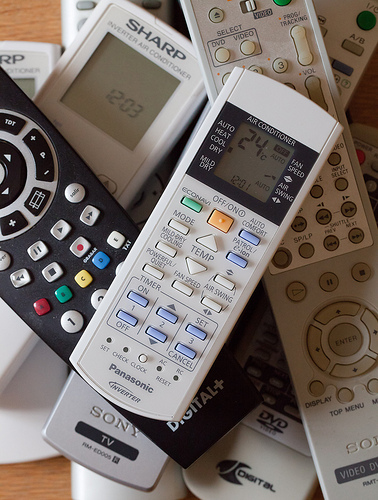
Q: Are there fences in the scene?
A: No, there are no fences.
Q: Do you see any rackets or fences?
A: No, there are no fences or rackets.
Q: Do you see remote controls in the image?
A: Yes, there is a remote control.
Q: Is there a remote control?
A: Yes, there is a remote control.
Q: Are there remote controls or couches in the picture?
A: Yes, there is a remote control.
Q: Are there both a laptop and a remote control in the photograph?
A: No, there is a remote control but no laptops.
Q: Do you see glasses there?
A: No, there are no glasses.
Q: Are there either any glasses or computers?
A: No, there are no glasses or computers.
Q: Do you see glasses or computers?
A: No, there are no glasses or computers.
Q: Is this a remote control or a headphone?
A: This is a remote control.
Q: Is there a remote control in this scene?
A: Yes, there is a remote control.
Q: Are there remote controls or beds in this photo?
A: Yes, there is a remote control.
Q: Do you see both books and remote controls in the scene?
A: No, there is a remote control but no books.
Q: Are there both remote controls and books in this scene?
A: No, there is a remote control but no books.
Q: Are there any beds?
A: No, there are no beds.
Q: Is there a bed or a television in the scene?
A: No, there are no beds or televisions.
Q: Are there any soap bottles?
A: No, there are no soap bottles.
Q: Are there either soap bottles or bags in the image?
A: No, there are no soap bottles or bags.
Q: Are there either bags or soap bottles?
A: No, there are no soap bottles or bags.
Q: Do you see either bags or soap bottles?
A: No, there are no soap bottles or bags.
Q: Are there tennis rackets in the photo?
A: No, there are no tennis rackets.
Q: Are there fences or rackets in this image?
A: No, there are no rackets or fences.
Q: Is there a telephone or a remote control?
A: Yes, there is a remote control.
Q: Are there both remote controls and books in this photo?
A: No, there is a remote control but no books.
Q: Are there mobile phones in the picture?
A: No, there are no mobile phones.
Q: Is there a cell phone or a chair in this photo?
A: No, there are no cell phones or chairs.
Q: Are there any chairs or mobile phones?
A: No, there are no mobile phones or chairs.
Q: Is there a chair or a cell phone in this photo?
A: No, there are no cell phones or chairs.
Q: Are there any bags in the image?
A: No, there are no bags.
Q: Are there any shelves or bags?
A: No, there are no bags or shelves.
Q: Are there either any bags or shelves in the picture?
A: No, there are no bags or shelves.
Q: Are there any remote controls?
A: Yes, there is a remote control.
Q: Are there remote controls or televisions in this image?
A: Yes, there is a remote control.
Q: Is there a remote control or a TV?
A: Yes, there is a remote control.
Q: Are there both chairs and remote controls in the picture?
A: No, there is a remote control but no chairs.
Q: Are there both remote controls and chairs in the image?
A: No, there is a remote control but no chairs.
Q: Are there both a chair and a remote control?
A: No, there is a remote control but no chairs.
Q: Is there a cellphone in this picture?
A: No, there are no cell phones.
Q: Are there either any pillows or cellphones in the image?
A: No, there are no cellphones or pillows.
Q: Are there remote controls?
A: Yes, there is a remote control.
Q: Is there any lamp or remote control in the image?
A: Yes, there is a remote control.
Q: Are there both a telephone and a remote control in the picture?
A: No, there is a remote control but no phones.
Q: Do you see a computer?
A: No, there are no computers.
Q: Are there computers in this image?
A: No, there are no computers.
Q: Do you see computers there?
A: No, there are no computers.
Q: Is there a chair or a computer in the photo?
A: No, there are no computers or chairs.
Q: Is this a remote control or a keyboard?
A: This is a remote control.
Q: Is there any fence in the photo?
A: No, there are no fences.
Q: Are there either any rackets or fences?
A: No, there are no fences or rackets.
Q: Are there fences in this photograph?
A: No, there are no fences.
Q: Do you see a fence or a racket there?
A: No, there are no fences or rackets.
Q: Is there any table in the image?
A: Yes, there is a table.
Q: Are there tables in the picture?
A: Yes, there is a table.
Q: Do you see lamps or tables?
A: Yes, there is a table.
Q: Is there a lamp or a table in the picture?
A: Yes, there is a table.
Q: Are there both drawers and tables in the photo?
A: No, there is a table but no drawers.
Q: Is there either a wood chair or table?
A: Yes, there is a wood table.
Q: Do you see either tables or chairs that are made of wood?
A: Yes, the table is made of wood.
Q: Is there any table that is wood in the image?
A: Yes, there is a wood table.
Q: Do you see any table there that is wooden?
A: Yes, there is a table that is wooden.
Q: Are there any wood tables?
A: Yes, there is a table that is made of wood.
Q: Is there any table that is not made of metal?
A: Yes, there is a table that is made of wood.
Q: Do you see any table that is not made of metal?
A: Yes, there is a table that is made of wood.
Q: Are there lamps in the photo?
A: No, there are no lamps.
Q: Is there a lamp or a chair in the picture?
A: No, there are no lamps or chairs.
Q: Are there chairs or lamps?
A: No, there are no lamps or chairs.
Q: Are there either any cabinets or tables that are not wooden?
A: No, there is a table but it is wooden.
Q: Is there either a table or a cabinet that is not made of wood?
A: No, there is a table but it is made of wood.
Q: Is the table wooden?
A: Yes, the table is wooden.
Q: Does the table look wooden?
A: Yes, the table is wooden.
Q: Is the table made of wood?
A: Yes, the table is made of wood.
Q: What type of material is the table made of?
A: The table is made of wood.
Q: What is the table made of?
A: The table is made of wood.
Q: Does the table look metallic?
A: No, the table is wooden.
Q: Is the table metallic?
A: No, the table is wooden.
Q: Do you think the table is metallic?
A: No, the table is wooden.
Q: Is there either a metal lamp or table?
A: No, there is a table but it is wooden.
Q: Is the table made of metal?
A: No, the table is made of wood.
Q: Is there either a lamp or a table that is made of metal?
A: No, there is a table but it is made of wood.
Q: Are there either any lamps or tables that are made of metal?
A: No, there is a table but it is made of wood.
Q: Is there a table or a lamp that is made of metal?
A: No, there is a table but it is made of wood.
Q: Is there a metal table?
A: No, there is a table but it is made of wood.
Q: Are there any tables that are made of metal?
A: No, there is a table but it is made of wood.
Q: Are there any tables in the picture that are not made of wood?
A: No, there is a table but it is made of wood.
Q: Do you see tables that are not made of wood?
A: No, there is a table but it is made of wood.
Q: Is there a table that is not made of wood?
A: No, there is a table but it is made of wood.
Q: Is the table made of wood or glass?
A: The table is made of wood.